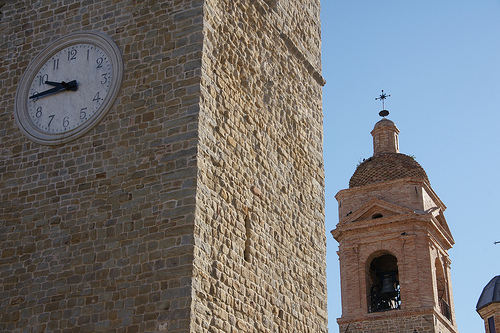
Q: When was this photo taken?
A: 9:45am.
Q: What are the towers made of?
A: Brick.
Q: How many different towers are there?
A: Two.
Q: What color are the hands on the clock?
A: They are black.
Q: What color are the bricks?
A: Tan.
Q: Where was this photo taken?
A: In a town.